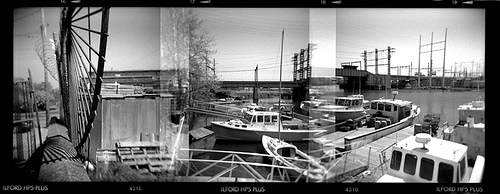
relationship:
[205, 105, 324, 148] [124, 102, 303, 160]
ship on water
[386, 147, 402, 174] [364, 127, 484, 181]
window on boat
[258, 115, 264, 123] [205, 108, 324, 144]
window on boat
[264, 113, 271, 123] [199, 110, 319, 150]
window on boat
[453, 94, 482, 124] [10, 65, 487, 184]
boat parked in pier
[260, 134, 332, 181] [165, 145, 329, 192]
boat parked next to dock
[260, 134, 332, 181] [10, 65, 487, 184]
boat in pier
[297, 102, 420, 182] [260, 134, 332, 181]
pier by boat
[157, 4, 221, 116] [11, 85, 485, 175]
tree in middle of pier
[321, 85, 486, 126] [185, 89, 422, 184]
water off pier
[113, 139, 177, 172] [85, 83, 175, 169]
pallets leaning against building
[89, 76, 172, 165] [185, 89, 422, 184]
shack near pier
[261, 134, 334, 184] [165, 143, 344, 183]
boat near fencing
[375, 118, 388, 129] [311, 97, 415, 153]
box in boat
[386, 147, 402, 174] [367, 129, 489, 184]
window on boat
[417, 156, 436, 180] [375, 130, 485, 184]
window on boat